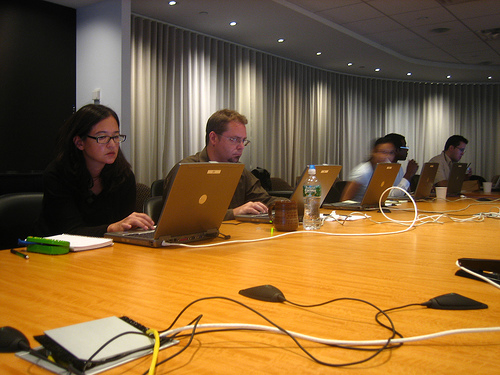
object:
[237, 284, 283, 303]
mouse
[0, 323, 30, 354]
mouse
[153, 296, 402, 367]
cord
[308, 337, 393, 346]
wire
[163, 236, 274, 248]
cord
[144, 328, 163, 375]
cord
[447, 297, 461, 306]
black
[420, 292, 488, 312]
mouse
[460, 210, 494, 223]
ethernet cord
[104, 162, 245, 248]
laptop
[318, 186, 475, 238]
cord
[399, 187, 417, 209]
ethernet cord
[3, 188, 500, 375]
desk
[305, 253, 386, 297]
part